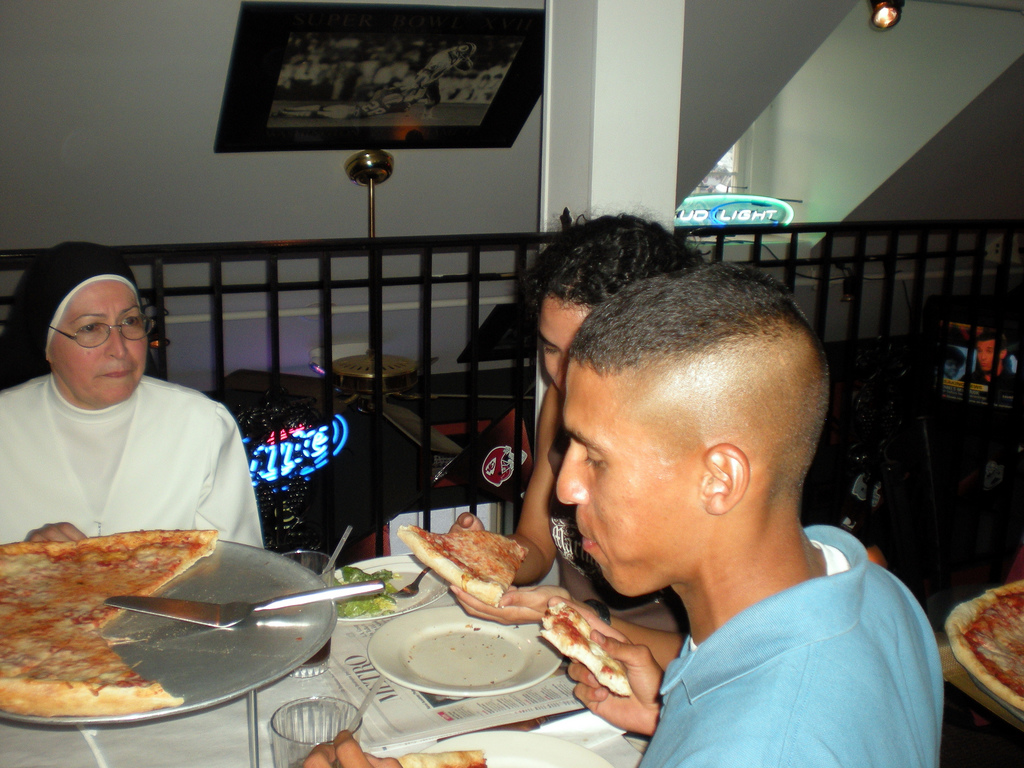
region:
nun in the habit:
[2, 234, 281, 532]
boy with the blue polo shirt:
[545, 287, 950, 766]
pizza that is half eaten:
[1, 525, 337, 722]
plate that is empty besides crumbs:
[370, 609, 561, 714]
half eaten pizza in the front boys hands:
[550, 600, 648, 680]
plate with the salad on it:
[336, 553, 450, 623]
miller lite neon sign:
[219, 397, 375, 484]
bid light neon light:
[655, 179, 804, 252]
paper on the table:
[304, 556, 595, 763]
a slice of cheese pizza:
[397, 525, 530, 611]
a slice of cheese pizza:
[544, 599, 628, 692]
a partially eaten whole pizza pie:
[6, 535, 336, 723]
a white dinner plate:
[373, 606, 564, 698]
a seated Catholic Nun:
[0, 244, 266, 558]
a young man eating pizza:
[285, 271, 940, 766]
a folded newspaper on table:
[331, 593, 572, 746]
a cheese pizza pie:
[945, 579, 1022, 715]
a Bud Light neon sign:
[676, 194, 794, 233]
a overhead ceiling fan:
[211, 154, 528, 459]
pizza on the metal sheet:
[1, 528, 363, 731]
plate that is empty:
[373, 601, 566, 707]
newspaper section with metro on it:
[318, 556, 595, 738]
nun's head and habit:
[5, 231, 155, 410]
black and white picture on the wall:
[204, 3, 556, 159]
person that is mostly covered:
[491, 218, 714, 393]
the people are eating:
[4, 203, 969, 751]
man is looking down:
[403, 273, 838, 558]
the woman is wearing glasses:
[8, 210, 259, 476]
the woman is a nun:
[8, 223, 271, 552]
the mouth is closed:
[547, 482, 630, 593]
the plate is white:
[348, 569, 568, 716]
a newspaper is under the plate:
[298, 573, 575, 725]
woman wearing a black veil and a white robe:
[0, 239, 263, 554]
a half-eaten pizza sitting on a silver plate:
[0, 529, 336, 723]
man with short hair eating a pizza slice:
[299, 277, 939, 767]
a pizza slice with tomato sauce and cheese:
[402, 519, 526, 606]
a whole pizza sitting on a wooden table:
[934, 581, 1021, 762]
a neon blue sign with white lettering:
[677, 195, 791, 235]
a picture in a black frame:
[212, 7, 544, 154]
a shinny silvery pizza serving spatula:
[105, 580, 382, 628]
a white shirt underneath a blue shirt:
[637, 517, 941, 762]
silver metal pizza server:
[103, 579, 397, 634]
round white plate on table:
[375, 601, 553, 696]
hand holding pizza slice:
[541, 609, 650, 702]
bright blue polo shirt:
[644, 540, 958, 760]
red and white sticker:
[479, 435, 522, 494]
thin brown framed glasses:
[51, 309, 163, 352]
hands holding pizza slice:
[392, 511, 532, 609]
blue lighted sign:
[239, 421, 367, 488]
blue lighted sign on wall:
[678, 187, 799, 242]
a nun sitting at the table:
[2, 238, 266, 552]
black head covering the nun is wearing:
[0, 238, 137, 390]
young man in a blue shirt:
[297, 262, 943, 766]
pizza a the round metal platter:
[2, 528, 336, 726]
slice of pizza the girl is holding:
[395, 521, 528, 610]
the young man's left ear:
[701, 445, 752, 518]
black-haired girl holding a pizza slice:
[448, 214, 706, 680]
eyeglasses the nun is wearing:
[47, 309, 153, 351]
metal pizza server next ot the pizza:
[106, 575, 385, 629]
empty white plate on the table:
[366, 603, 564, 696]